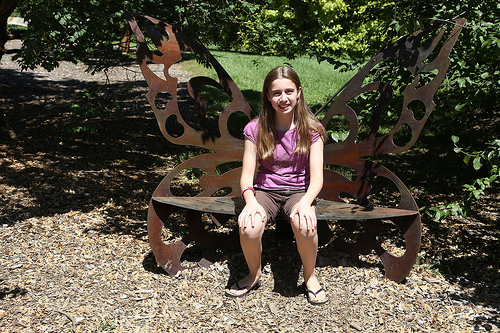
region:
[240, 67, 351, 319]
a girl sitting in the sitting bench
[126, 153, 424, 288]
sitting bench made with metal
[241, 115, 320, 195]
girl wearing pink color shirt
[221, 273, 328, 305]
girl wearing slipper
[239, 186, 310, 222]
girl wearing brown color shorts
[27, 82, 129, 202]
shadow of the tree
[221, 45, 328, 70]
dirt and green grass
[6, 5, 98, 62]
tree with branches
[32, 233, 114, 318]
dirt with dried leafs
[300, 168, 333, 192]
elbow of the girl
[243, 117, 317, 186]
purple cotton tee shirt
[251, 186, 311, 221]
brown cotton girls shorts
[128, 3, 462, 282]
brown metal park bench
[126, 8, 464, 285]
butterfly shaped park bench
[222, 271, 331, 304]
black rubber flip flops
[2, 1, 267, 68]
tree with green leaves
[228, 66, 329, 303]
girl sitting on bench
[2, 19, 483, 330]
mulch covered park area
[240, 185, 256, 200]
pink bracelet on wrist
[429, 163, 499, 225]
branch with green leaves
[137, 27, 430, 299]
she is sitting on the bench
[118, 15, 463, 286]
the bench looks like a butterfly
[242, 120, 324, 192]
she wears a pink blouse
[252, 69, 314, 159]
a long blond hair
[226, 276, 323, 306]
the feet of the girl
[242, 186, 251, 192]
a pink bracelet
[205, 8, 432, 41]
green leaves in the background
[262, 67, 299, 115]
the head of the girl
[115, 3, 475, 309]
A girl sitting on a bench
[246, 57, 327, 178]
The girl has long brown hair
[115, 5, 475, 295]
The bench is shaped like a butterfly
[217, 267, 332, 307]
A pair of black flip flops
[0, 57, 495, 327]
Shadows are on the ground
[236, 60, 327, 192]
Girl wearing a purple shirt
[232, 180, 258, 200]
Pink bracelet around an arm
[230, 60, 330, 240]
Girl has her hands on her knees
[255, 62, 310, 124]
The girl is smiling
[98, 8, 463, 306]
A young girl sitting on a butterfly bench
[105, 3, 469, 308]
A young girl sitting on a butterfly bench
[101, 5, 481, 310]
A young girl sitting on a butterfly bench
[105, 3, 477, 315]
A young girl sitting on a butterfly bench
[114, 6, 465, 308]
A young girl sitting on a butterfly bench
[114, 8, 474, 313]
A young girl sitting on a butterfly bench